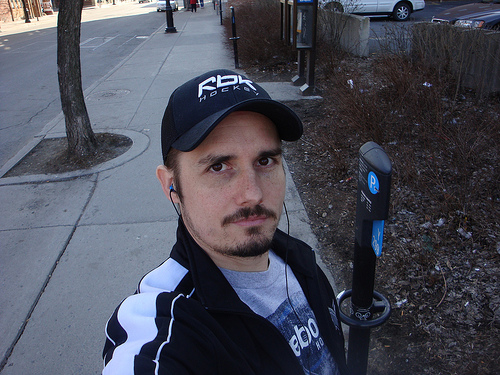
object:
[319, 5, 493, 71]
lot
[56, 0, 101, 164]
tree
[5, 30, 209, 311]
sidewalk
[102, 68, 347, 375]
man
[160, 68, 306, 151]
cap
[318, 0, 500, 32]
vehicles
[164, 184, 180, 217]
earbud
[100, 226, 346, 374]
jacket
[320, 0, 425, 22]
vehicle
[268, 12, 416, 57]
divider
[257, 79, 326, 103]
foundation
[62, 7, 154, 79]
parking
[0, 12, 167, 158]
street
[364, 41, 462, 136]
shrubs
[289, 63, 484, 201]
wintertime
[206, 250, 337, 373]
shirt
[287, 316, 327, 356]
logo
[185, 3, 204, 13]
pedestrian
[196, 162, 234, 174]
eye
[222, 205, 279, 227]
mustache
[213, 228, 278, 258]
goatee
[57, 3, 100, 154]
trunk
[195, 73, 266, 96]
letter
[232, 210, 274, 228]
lip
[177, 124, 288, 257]
face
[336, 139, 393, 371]
pole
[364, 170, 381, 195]
object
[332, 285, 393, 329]
hubcap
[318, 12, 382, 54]
wall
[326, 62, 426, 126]
weeds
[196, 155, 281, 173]
eyes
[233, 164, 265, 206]
nose